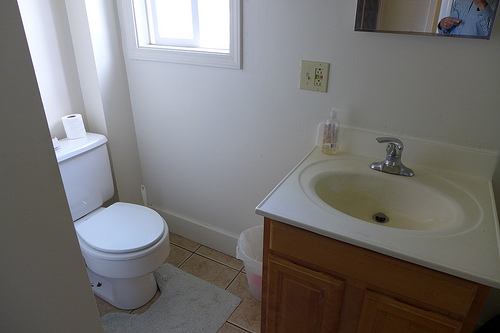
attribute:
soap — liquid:
[322, 104, 341, 169]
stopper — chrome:
[374, 207, 389, 222]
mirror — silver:
[349, 3, 496, 37]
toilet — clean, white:
[38, 106, 175, 324]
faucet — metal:
[370, 135, 414, 176]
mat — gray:
[87, 265, 257, 332]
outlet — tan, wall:
[299, 59, 331, 95]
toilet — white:
[36, 118, 181, 315]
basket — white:
[231, 224, 263, 301]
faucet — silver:
[364, 102, 436, 198]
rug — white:
[99, 250, 238, 331]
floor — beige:
[36, 162, 271, 332]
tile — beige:
[167, 244, 255, 289]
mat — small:
[97, 264, 243, 332]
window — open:
[123, 15, 275, 87]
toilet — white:
[49, 121, 229, 329]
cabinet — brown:
[258, 214, 490, 331]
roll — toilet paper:
[57, 109, 89, 145]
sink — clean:
[311, 166, 464, 234]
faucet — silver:
[372, 133, 411, 173]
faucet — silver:
[368, 134, 417, 181]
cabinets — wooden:
[261, 243, 364, 330]